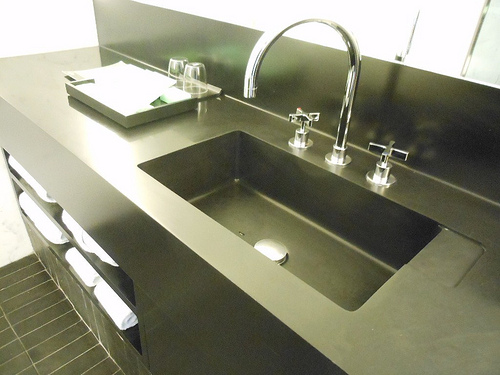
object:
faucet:
[241, 10, 364, 167]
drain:
[253, 236, 291, 267]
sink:
[137, 128, 442, 313]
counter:
[0, 45, 500, 374]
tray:
[65, 68, 202, 130]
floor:
[0, 252, 127, 374]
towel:
[16, 190, 68, 244]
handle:
[286, 107, 321, 151]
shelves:
[9, 168, 139, 319]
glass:
[180, 61, 210, 97]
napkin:
[92, 58, 180, 105]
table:
[0, 45, 500, 375]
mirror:
[137, 0, 500, 91]